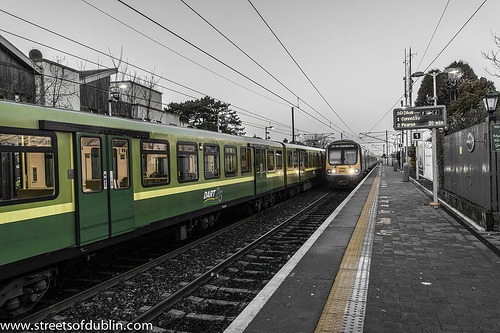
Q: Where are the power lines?
A: Power lines above the trains.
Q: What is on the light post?
A: A sign on the street light post.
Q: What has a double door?
A: The train has a double door.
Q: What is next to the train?
A: A walkway next to the train.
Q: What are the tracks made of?
A: The train tracks are metal.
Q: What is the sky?
A: The sky is gray.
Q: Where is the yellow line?
A: On the platform.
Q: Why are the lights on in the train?
A: Because the sky is overcast.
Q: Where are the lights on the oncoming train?
A: On the front.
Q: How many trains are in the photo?
A: Two.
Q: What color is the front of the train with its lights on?
A: Yellow.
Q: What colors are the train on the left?
A: Green and yellow.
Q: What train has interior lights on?
A: The left one.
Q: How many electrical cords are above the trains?
A: Nine.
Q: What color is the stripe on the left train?
A: Yellow.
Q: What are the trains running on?
A: Tracks.